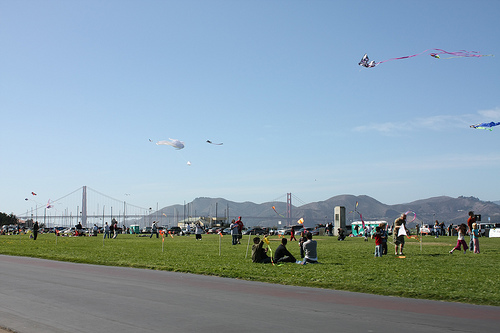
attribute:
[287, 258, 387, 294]
field — part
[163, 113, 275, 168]
kite — flying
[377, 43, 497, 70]
pink tails — long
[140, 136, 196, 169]
kite — flying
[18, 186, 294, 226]
bridge — large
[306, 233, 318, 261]
person — sitting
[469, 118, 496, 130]
kite — blue, green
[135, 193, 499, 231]
mountains — grey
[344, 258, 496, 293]
field — green, grassy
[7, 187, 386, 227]
bridge — long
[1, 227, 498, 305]
grass — green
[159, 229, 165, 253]
flag — orange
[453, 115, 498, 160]
kite — flying